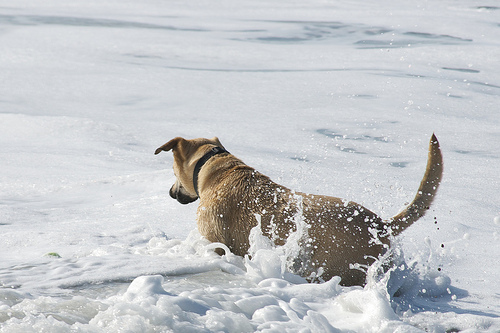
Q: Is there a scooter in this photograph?
A: No, there are no scooters.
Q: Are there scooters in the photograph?
A: No, there are no scooters.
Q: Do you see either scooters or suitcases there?
A: No, there are no scooters or suitcases.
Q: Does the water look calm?
A: Yes, the water is calm.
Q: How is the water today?
A: The water is calm.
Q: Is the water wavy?
A: No, the water is calm.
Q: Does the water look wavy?
A: No, the water is calm.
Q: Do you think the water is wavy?
A: No, the water is calm.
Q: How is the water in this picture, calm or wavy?
A: The water is calm.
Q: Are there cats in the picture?
A: No, there are no cats.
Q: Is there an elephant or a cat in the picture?
A: No, there are no cats or elephants.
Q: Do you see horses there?
A: No, there are no horses.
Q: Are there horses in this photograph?
A: No, there are no horses.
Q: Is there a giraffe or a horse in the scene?
A: No, there are no horses or giraffes.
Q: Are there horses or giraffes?
A: No, there are no horses or giraffes.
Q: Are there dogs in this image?
A: Yes, there is a dog.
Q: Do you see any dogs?
A: Yes, there is a dog.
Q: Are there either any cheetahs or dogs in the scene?
A: Yes, there is a dog.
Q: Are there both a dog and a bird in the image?
A: No, there is a dog but no birds.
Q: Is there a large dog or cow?
A: Yes, there is a large dog.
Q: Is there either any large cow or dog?
A: Yes, there is a large dog.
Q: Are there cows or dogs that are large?
A: Yes, the dog is large.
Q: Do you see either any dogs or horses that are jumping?
A: Yes, the dog is jumping.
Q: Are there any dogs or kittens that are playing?
A: Yes, the dog is playing.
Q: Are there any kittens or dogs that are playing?
A: Yes, the dog is playing.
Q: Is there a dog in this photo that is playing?
A: Yes, there is a dog that is playing.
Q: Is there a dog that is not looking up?
A: Yes, there is a dog that is playing.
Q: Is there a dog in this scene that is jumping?
A: Yes, there is a dog that is jumping.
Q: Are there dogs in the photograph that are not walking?
A: Yes, there is a dog that is jumping.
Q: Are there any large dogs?
A: Yes, there is a large dog.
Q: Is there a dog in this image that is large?
A: Yes, there is a dog that is large.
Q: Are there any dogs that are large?
A: Yes, there is a dog that is large.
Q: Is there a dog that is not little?
A: Yes, there is a large dog.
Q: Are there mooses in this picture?
A: No, there are no mooses.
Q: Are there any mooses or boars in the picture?
A: No, there are no mooses or boars.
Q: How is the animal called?
A: The animal is a dog.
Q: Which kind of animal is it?
A: The animal is a dog.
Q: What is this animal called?
A: This is a dog.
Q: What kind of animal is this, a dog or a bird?
A: This is a dog.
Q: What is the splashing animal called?
A: The animal is a dog.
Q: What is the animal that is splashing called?
A: The animal is a dog.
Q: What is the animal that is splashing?
A: The animal is a dog.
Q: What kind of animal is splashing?
A: The animal is a dog.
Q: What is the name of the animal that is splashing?
A: The animal is a dog.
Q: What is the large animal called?
A: The animal is a dog.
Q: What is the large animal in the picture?
A: The animal is a dog.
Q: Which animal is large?
A: The animal is a dog.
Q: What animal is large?
A: The animal is a dog.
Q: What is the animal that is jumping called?
A: The animal is a dog.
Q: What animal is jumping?
A: The animal is a dog.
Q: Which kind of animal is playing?
A: The animal is a dog.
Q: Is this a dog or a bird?
A: This is a dog.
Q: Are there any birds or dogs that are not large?
A: No, there is a dog but it is large.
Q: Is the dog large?
A: Yes, the dog is large.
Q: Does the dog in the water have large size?
A: Yes, the dog is large.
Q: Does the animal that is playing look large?
A: Yes, the dog is large.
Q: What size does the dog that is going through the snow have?
A: The dog has large size.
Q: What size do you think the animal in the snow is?
A: The dog is large.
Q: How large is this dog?
A: The dog is large.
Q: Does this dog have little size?
A: No, the dog is large.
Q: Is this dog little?
A: No, the dog is large.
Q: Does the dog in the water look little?
A: No, the dog is large.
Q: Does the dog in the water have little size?
A: No, the dog is large.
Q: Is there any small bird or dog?
A: No, there is a dog but it is large.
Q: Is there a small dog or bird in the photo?
A: No, there is a dog but it is large.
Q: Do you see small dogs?
A: No, there is a dog but it is large.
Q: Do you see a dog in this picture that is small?
A: No, there is a dog but it is large.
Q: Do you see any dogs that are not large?
A: No, there is a dog but it is large.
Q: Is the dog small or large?
A: The dog is large.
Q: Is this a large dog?
A: Yes, this is a large dog.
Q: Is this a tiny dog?
A: No, this is a large dog.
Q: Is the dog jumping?
A: Yes, the dog is jumping.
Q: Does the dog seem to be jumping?
A: Yes, the dog is jumping.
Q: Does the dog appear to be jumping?
A: Yes, the dog is jumping.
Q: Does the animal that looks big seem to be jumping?
A: Yes, the dog is jumping.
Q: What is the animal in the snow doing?
A: The dog is jumping.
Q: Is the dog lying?
A: No, the dog is jumping.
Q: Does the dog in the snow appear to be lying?
A: No, the dog is jumping.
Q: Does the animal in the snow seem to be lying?
A: No, the dog is jumping.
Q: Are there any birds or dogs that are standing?
A: No, there is a dog but it is jumping.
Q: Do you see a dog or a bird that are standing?
A: No, there is a dog but it is jumping.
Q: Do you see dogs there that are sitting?
A: No, there is a dog but it is jumping.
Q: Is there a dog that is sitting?
A: No, there is a dog but it is jumping.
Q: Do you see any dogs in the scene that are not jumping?
A: No, there is a dog but it is jumping.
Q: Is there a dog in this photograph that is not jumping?
A: No, there is a dog but it is jumping.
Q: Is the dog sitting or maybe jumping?
A: The dog is jumping.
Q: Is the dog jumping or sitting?
A: The dog is jumping.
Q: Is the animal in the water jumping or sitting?
A: The dog is jumping.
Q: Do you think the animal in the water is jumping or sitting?
A: The dog is jumping.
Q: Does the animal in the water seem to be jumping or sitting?
A: The dog is jumping.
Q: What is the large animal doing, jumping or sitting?
A: The dog is jumping.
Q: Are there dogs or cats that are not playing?
A: No, there is a dog but it is playing.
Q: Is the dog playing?
A: Yes, the dog is playing.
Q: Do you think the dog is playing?
A: Yes, the dog is playing.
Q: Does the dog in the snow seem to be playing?
A: Yes, the dog is playing.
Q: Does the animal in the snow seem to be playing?
A: Yes, the dog is playing.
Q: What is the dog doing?
A: The dog is playing.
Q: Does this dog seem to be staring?
A: No, the dog is playing.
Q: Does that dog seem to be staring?
A: No, the dog is playing.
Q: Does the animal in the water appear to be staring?
A: No, the dog is playing.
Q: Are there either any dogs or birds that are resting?
A: No, there is a dog but it is playing.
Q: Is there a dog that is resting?
A: No, there is a dog but it is playing.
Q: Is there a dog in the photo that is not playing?
A: No, there is a dog but it is playing.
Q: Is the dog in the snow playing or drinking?
A: The dog is playing.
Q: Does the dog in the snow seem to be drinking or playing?
A: The dog is playing.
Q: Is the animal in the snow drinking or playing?
A: The dog is playing.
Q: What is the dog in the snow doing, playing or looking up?
A: The dog is playing.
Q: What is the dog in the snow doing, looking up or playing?
A: The dog is playing.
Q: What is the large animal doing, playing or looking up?
A: The dog is playing.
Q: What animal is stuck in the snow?
A: The dog is stuck in the snow.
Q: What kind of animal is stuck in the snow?
A: The animal is a dog.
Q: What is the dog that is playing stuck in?
A: The dog is stuck in the snow.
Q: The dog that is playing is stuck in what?
A: The dog is stuck in the snow.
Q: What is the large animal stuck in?
A: The dog is stuck in the snow.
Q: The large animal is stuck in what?
A: The dog is stuck in the snow.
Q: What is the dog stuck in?
A: The dog is stuck in the snow.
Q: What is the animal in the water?
A: The animal is a dog.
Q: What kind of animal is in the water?
A: The animal is a dog.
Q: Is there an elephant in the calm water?
A: No, there is a dog in the water.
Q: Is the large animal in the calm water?
A: Yes, the dog is in the water.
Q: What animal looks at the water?
A: The dog looks at the water.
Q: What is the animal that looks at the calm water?
A: The animal is a dog.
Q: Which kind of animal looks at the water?
A: The animal is a dog.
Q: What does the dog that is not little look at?
A: The dog looks at the water.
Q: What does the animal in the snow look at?
A: The dog looks at the water.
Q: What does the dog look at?
A: The dog looks at the water.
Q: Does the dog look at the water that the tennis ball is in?
A: Yes, the dog looks at the water.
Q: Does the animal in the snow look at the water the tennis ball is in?
A: Yes, the dog looks at the water.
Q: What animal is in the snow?
A: The animal is a dog.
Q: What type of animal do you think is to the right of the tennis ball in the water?
A: The animal is a dog.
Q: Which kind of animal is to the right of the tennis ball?
A: The animal is a dog.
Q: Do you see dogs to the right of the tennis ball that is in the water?
A: Yes, there is a dog to the right of the tennis ball.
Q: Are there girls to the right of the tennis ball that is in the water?
A: No, there is a dog to the right of the tennis ball.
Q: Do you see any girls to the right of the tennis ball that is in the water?
A: No, there is a dog to the right of the tennis ball.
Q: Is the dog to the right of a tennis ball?
A: Yes, the dog is to the right of a tennis ball.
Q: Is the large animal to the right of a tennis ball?
A: Yes, the dog is to the right of a tennis ball.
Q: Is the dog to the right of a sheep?
A: No, the dog is to the right of a tennis ball.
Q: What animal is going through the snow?
A: The dog is going through the snow.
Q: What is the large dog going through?
A: The dog is going through the snow.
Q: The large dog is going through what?
A: The dog is going through the snow.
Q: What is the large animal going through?
A: The dog is going through the snow.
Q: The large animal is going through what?
A: The dog is going through the snow.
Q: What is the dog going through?
A: The dog is going through the snow.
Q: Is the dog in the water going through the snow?
A: Yes, the dog is going through the snow.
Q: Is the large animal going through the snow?
A: Yes, the dog is going through the snow.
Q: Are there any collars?
A: Yes, there is a collar.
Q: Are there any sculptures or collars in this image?
A: Yes, there is a collar.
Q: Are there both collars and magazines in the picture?
A: No, there is a collar but no magazines.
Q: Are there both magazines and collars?
A: No, there is a collar but no magazines.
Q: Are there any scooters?
A: No, there are no scooters.